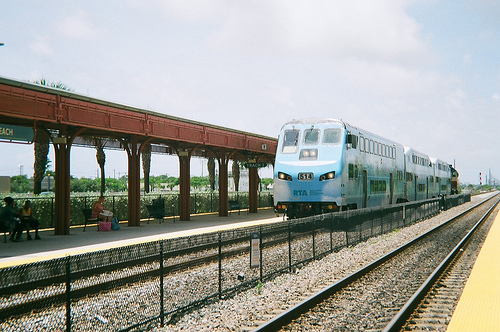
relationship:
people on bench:
[93, 195, 106, 220] [80, 206, 101, 234]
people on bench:
[22, 197, 42, 240] [0, 211, 37, 243]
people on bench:
[0, 195, 20, 243] [0, 211, 37, 243]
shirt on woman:
[22, 205, 32, 218] [22, 197, 42, 240]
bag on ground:
[100, 221, 114, 231] [0, 203, 287, 262]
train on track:
[270, 115, 459, 219] [0, 188, 499, 331]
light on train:
[278, 171, 284, 179] [270, 115, 459, 219]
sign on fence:
[248, 230, 262, 268] [3, 191, 476, 331]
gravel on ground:
[1, 188, 499, 330] [0, 203, 287, 262]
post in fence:
[217, 230, 225, 299] [3, 191, 476, 331]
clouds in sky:
[2, 4, 492, 184] [1, 3, 499, 176]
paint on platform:
[0, 245, 77, 275] [0, 200, 280, 273]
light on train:
[329, 171, 334, 180] [270, 115, 459, 219]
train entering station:
[270, 115, 459, 219] [1, 68, 496, 325]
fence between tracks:
[3, 191, 476, 331] [0, 188, 499, 331]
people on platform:
[93, 195, 106, 220] [0, 200, 280, 273]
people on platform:
[22, 197, 42, 240] [0, 200, 280, 273]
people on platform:
[0, 195, 20, 243] [0, 200, 280, 273]